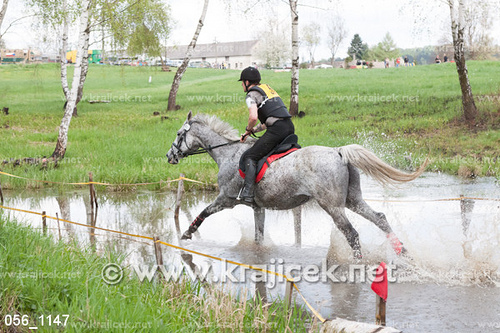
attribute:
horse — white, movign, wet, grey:
[156, 110, 413, 264]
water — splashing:
[143, 219, 472, 288]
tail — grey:
[345, 134, 426, 192]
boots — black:
[238, 156, 267, 208]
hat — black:
[238, 63, 266, 83]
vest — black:
[250, 82, 292, 126]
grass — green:
[106, 123, 145, 169]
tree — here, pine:
[41, 4, 100, 160]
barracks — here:
[75, 210, 229, 295]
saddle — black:
[272, 128, 304, 155]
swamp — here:
[56, 177, 170, 276]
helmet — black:
[240, 60, 256, 91]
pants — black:
[242, 122, 287, 170]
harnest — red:
[180, 140, 298, 170]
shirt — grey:
[244, 90, 273, 110]